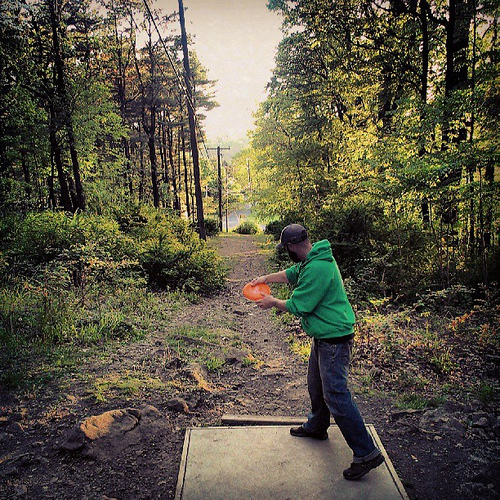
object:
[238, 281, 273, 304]
frisbee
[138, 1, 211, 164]
utility lines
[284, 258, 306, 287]
sleeves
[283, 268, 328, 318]
sleeves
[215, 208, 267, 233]
water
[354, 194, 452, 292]
vegetation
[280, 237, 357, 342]
green jacket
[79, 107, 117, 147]
leaves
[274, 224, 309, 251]
cap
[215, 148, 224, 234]
pole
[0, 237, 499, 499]
dirt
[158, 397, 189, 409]
rock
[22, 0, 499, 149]
gray sky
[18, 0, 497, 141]
clouds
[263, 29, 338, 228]
tree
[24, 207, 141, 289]
vegetation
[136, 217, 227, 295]
green vegetation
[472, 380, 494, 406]
green vegetation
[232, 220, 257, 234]
green vegetation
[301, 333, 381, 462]
blue jeans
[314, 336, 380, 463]
leg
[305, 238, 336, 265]
hood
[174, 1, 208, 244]
pole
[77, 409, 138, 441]
footprints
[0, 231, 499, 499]
path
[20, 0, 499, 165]
sky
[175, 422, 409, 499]
platform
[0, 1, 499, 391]
forest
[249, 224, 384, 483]
man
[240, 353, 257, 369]
green grass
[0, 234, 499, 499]
dirt path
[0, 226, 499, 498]
field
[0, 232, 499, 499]
ground